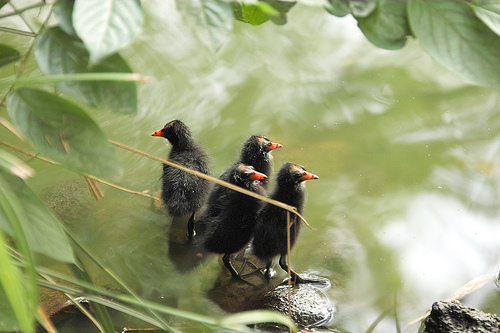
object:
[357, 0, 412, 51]
leaf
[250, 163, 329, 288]
bird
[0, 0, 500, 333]
plant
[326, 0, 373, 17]
leaf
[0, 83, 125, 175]
green leaf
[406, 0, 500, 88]
green leaf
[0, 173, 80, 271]
green leaf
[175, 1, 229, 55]
green leaf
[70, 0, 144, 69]
green leaf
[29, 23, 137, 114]
leaf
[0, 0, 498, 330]
tree